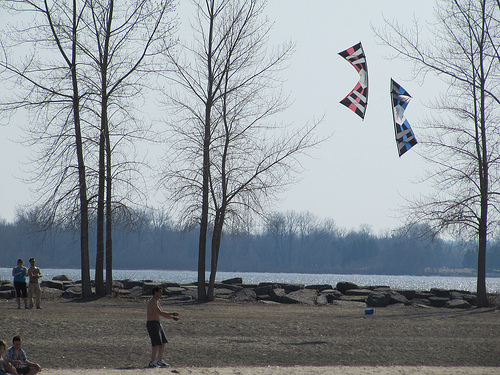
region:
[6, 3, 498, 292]
two kites fly above a lake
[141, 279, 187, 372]
a man is flying a kite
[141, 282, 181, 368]
man is wearing dark colored shorts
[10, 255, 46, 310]
two people stand by a lake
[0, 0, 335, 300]
two tall leafless trees next to a lake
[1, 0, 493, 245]
sky is pale blue and hazy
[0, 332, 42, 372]
two children sit on the ground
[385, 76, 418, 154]
kite is blue black and grey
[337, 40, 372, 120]
kite is red black and grey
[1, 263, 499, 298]
sun is glinting off the surface of a lake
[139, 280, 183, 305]
the head of a man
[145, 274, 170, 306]
the hair of a man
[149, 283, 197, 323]
the arm of a man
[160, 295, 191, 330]
the hand of a man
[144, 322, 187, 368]
the legs of a man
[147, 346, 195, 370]
the feet of a man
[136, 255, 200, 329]
a man with no shirt on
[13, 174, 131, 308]
people in the background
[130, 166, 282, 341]
a man near tree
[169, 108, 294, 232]
a tree with no leaves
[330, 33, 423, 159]
two kites being flown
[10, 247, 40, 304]
two men watching the kites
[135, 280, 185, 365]
man flying the kite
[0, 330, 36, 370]
people sitting next to the man flying the kite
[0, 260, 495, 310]
rock wall along water's edge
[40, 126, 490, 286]
trees along the water's edge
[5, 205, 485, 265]
trees on opposite bank of the lake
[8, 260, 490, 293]
lake in the background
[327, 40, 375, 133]
a red kite flying in the sky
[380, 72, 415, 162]
a blue kite flying in the sky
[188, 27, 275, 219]
barren trees without any leaves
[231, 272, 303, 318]
the coast of a lake lined with boulders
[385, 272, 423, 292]
a lake with a lot of ripples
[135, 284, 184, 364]
a man that is not wearing a shirt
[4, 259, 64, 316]
two adults standing with each other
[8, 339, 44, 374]
a child that is sitting on the ground